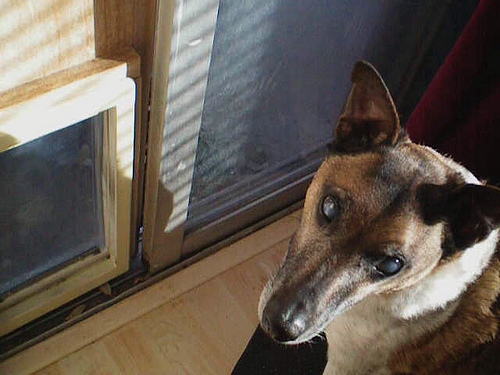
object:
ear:
[453, 179, 499, 246]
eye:
[316, 185, 344, 224]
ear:
[332, 59, 400, 148]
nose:
[256, 311, 305, 342]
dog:
[256, 60, 499, 374]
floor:
[0, 206, 303, 375]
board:
[0, 0, 156, 338]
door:
[141, 0, 448, 277]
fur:
[406, 239, 499, 333]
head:
[256, 57, 499, 346]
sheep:
[129, 207, 225, 266]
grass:
[209, 134, 238, 174]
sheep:
[121, 278, 200, 361]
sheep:
[130, 313, 217, 375]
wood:
[153, 295, 263, 375]